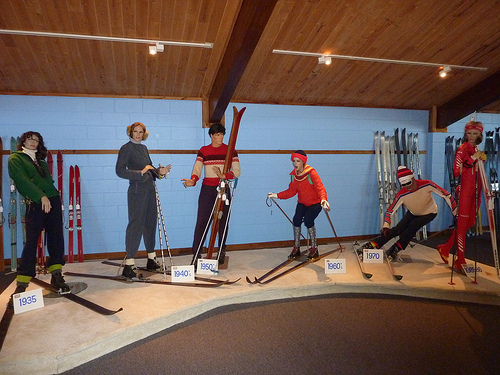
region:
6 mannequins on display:
[5, 102, 495, 334]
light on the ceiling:
[114, 24, 469, 78]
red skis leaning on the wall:
[57, 150, 95, 265]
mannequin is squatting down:
[255, 132, 347, 276]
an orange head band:
[277, 140, 312, 168]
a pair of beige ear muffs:
[114, 117, 157, 143]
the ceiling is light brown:
[271, 11, 436, 98]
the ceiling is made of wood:
[290, 17, 480, 98]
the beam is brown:
[204, 0, 271, 121]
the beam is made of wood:
[201, 12, 277, 132]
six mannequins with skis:
[14, 111, 488, 324]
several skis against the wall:
[356, 122, 426, 238]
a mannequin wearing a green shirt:
[8, 119, 57, 221]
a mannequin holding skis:
[187, 94, 252, 259]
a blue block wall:
[234, 110, 360, 187]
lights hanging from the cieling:
[64, 25, 479, 65]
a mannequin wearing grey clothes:
[109, 114, 167, 264]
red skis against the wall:
[42, 147, 91, 261]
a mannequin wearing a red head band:
[462, 109, 490, 158]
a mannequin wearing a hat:
[386, 161, 426, 205]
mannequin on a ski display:
[6, 66, 483, 318]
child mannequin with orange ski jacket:
[250, 130, 385, 290]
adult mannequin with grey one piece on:
[94, 89, 199, 294]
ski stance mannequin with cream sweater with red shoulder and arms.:
[329, 128, 444, 282]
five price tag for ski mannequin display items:
[2, 241, 437, 310]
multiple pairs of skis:
[343, 102, 436, 259]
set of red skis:
[61, 166, 101, 270]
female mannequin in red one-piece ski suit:
[442, 89, 489, 294]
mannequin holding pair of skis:
[173, 88, 250, 277]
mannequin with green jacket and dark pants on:
[0, 86, 115, 335]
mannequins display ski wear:
[1, 116, 498, 260]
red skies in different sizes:
[41, 147, 86, 262]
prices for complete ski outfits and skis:
[155, 245, 405, 285]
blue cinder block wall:
[22, 101, 197, 246]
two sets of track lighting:
[9, 27, 487, 84]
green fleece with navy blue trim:
[3, 142, 73, 204]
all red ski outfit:
[438, 113, 486, 277]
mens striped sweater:
[193, 141, 250, 188]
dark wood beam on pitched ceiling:
[144, 0, 319, 132]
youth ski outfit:
[256, 145, 339, 285]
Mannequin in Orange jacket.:
[270, 147, 353, 308]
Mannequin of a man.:
[190, 114, 237, 288]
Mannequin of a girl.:
[263, 141, 330, 303]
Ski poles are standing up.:
[137, 150, 185, 272]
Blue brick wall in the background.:
[74, 131, 116, 241]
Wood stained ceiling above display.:
[77, 9, 134, 89]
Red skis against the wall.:
[64, 152, 91, 266]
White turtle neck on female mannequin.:
[9, 121, 66, 236]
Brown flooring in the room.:
[215, 286, 294, 368]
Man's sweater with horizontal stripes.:
[187, 127, 259, 211]